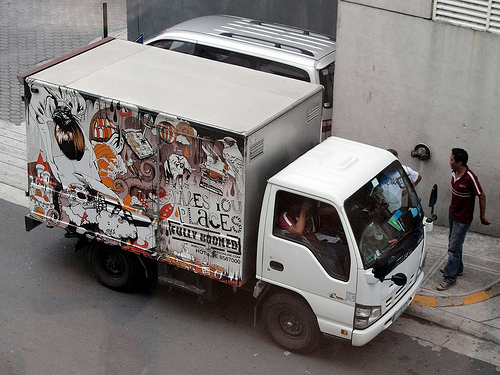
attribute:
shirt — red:
[445, 165, 485, 216]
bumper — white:
[346, 265, 429, 348]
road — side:
[7, 273, 295, 373]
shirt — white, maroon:
[279, 208, 317, 237]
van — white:
[139, 8, 354, 145]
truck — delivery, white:
[18, 37, 435, 348]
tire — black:
[65, 231, 159, 278]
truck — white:
[81, 81, 461, 368]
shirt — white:
[375, 167, 418, 209]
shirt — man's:
[443, 167, 477, 222]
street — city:
[38, 250, 125, 370]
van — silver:
[149, 5, 335, 142]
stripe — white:
[464, 169, 483, 194]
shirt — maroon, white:
[449, 168, 484, 227]